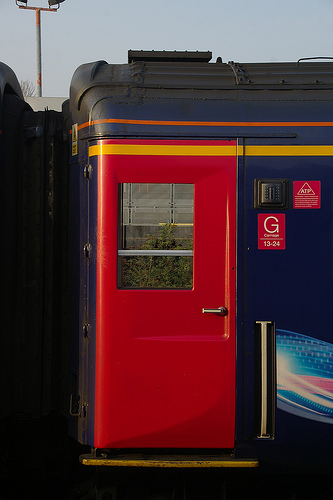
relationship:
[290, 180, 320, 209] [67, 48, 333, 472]
label attached to train car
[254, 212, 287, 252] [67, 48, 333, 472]
label attached to train car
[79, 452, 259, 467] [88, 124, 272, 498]
step underneath door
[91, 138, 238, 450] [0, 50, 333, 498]
door belongs to train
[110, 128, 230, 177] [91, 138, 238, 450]
yellow stripe painted on door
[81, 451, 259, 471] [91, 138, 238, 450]
platform underneath door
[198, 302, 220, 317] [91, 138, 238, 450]
handle attached to door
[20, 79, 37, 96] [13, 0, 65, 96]
bare trees standing behind light pole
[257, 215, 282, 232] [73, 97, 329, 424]
big g painted on side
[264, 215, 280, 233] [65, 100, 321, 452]
big g painted on side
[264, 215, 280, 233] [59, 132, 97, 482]
big g painted on side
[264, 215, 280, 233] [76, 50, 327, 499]
big g painted on side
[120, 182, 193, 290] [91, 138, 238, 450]
window on a door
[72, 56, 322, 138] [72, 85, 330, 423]
roof of a train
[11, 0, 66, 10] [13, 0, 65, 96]
flood lights on a light pole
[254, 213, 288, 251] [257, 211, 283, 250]
sign with letters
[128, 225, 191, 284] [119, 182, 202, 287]
tree reflection in window